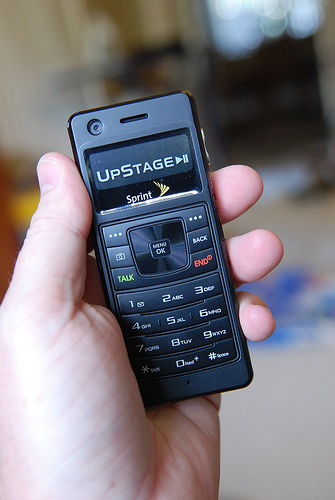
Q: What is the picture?
A: Phone.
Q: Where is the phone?
A: In a hand.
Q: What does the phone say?
A: Upstage.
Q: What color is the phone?
A: Black.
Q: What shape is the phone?
A: Rectangle.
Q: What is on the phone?
A: Buttons.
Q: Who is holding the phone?
A: A person.